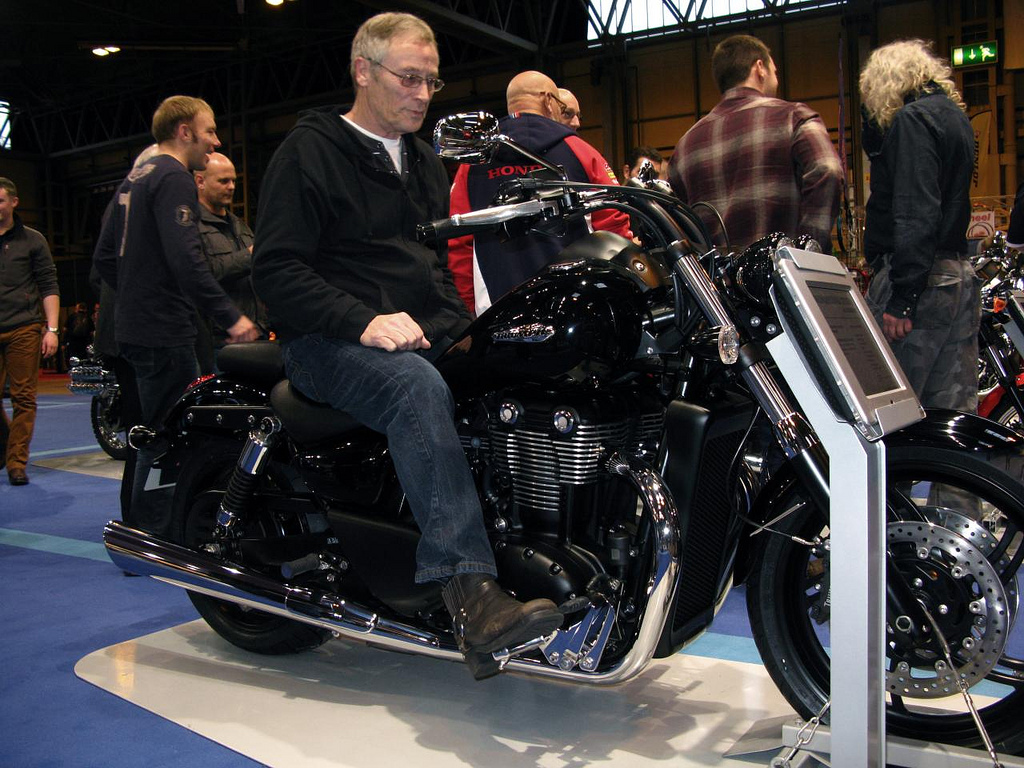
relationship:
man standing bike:
[681, 36, 837, 252] [69, 111, 1020, 749]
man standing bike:
[254, 12, 557, 683] [69, 111, 1020, 749]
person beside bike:
[624, 148, 675, 221] [69, 111, 1020, 749]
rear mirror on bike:
[427, 104, 565, 191] [69, 111, 1020, 749]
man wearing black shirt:
[189, 147, 276, 334] [853, 77, 985, 322]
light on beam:
[82, 34, 126, 69] [74, 28, 235, 61]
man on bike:
[189, 147, 276, 334] [90, 104, 1022, 751]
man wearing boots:
[242, 11, 577, 691] [448, 575, 551, 677]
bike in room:
[69, 111, 1020, 749] [8, 1, 1014, 755]